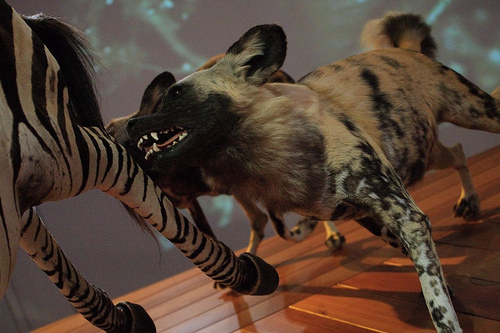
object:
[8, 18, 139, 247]
zebra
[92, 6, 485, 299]
light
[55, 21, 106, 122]
animal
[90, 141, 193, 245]
leg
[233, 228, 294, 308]
hoof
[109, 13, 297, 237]
mouth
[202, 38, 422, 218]
hyena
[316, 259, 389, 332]
table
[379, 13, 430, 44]
tail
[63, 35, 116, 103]
tail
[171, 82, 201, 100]
eye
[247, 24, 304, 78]
ear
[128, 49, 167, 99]
muzzle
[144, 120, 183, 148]
tooth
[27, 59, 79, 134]
stripe